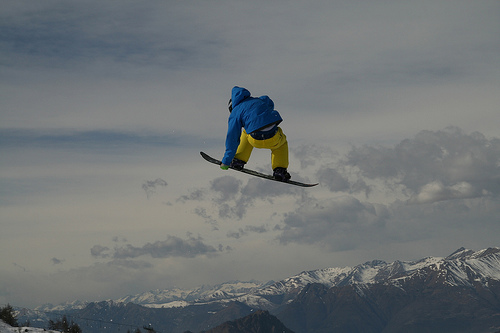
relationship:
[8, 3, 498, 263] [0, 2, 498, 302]
clouds in sky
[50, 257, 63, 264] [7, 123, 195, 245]
clouds in sky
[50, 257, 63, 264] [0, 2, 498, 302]
clouds in sky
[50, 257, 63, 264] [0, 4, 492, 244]
clouds in sky